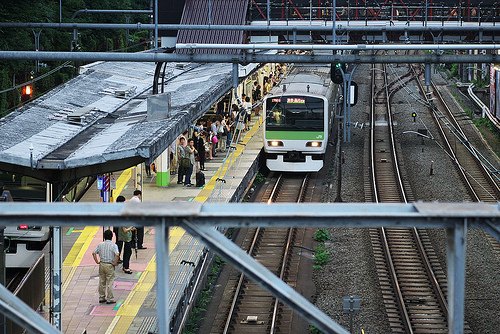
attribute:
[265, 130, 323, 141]
stripe — green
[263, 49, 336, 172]
train — white, green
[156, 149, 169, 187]
pole — green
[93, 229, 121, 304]
man — light skinned, standing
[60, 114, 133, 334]
line — yellow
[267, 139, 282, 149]
light — on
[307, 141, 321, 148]
light — on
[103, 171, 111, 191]
stripes — red, white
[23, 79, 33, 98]
lamp — on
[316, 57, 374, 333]
rocks — small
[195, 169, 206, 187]
bag — black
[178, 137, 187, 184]
person — waiting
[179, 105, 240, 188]
people — waiting, standing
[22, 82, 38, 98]
light — bright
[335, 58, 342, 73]
light — green